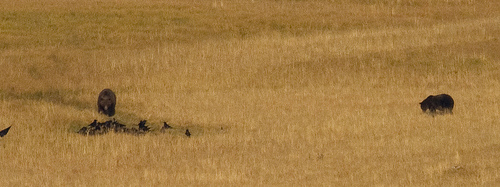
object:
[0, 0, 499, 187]
field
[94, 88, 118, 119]
bear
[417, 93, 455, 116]
bear